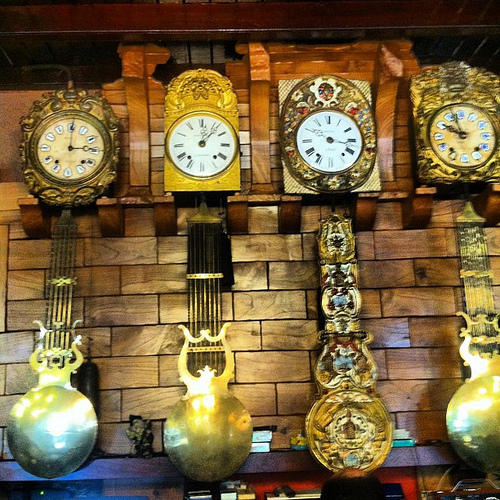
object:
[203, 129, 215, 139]
arm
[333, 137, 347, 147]
short hand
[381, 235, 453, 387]
wooden surface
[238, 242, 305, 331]
brick wall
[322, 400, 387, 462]
images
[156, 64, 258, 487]
clock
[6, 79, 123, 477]
clock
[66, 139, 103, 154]
black hands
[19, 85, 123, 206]
clock face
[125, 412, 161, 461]
figure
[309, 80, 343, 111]
gemstones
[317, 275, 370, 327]
decoration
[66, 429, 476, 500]
shelf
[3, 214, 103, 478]
pendulum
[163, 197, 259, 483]
pendulum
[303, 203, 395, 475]
pendulum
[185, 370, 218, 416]
spot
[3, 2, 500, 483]
wall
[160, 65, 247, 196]
clock